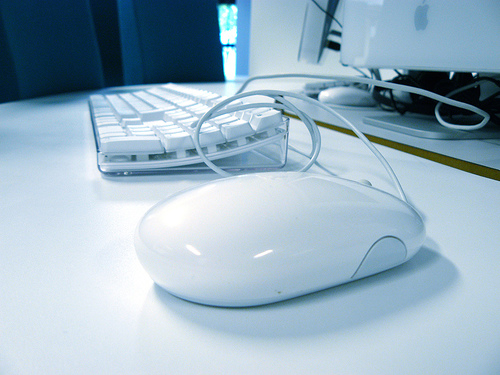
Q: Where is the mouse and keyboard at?
A: On white table.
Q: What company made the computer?
A: Apple.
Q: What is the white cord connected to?
A: Mouse and computer.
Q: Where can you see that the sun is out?
A: Crack in window.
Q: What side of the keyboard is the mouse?
A: Right.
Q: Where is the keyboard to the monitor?
A: Right side.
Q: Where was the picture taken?
A: In a office.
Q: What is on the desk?
A: A computer.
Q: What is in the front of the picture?
A: A computer mouse.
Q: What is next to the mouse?
A: Keyboard.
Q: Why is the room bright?
A: The light is on.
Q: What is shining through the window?
A: The sun.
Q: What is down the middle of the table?
A: A crack.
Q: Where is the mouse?
A: To the right of the keyboard.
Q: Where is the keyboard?
A: Behind the mouse.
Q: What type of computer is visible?
A: Apple.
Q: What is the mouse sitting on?
A: A desk.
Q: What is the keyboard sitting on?
A: A desk.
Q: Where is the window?
A: Behind the computer desk.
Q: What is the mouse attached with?
A: A cord.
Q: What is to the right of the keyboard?
A: A computer mouse.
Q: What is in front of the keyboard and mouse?
A: A computer.